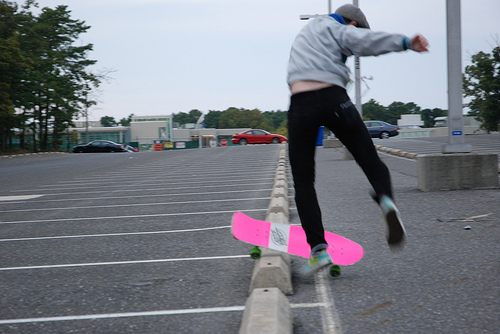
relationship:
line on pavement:
[0, 254, 251, 270] [11, 166, 217, 324]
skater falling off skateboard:
[279, 3, 431, 285] [225, 203, 367, 273]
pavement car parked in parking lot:
[232, 129, 288, 146] [0, 150, 498, 331]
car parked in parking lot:
[72, 139, 124, 154] [0, 150, 498, 331]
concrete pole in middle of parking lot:
[439, 1, 475, 158] [0, 150, 498, 331]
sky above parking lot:
[96, 10, 283, 105] [0, 150, 498, 331]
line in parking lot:
[0, 254, 251, 270] [0, 150, 498, 331]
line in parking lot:
[0, 251, 258, 273] [2, 131, 496, 332]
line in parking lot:
[91, 221, 164, 246] [0, 150, 498, 331]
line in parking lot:
[25, 175, 280, 193] [0, 150, 498, 331]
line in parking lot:
[66, 180, 156, 215] [0, 150, 498, 331]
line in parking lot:
[0, 302, 245, 322] [1, 139, 343, 332]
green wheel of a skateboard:
[246, 248, 262, 260] [178, 179, 405, 301]